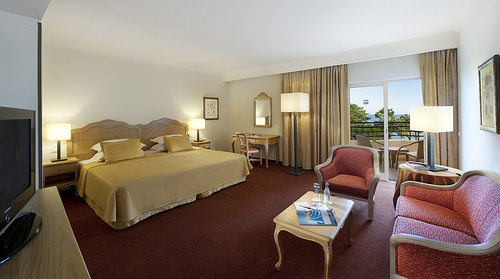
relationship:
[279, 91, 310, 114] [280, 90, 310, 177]
lamp shade top of floor lamp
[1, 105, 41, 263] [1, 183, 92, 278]
television on top of table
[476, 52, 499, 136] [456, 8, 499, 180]
art mounted on wall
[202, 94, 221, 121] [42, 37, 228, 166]
art mounted on wall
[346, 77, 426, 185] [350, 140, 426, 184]
french doors leading to deck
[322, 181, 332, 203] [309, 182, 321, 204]
bottle next to glass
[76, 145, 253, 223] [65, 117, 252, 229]
bed spread on top of bed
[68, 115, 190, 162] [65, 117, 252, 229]
headboard on back of bed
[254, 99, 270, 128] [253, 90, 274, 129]
mirror has frame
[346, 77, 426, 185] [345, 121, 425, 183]
french doors looking out to balcony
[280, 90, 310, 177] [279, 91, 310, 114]
floor lamp with lamp shade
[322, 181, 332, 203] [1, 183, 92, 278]
bottle on top of table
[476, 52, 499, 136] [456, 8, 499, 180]
art hanging on wall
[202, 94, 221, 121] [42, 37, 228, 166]
art hanging on wall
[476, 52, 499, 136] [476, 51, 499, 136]
art has frame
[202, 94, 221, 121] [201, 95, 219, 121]
art has frame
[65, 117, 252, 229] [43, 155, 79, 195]
bed next to nightstand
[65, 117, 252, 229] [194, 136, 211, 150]
bed next to nightstand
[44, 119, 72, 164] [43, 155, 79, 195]
lamp on top of nightstand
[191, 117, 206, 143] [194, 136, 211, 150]
lamp on top of nightstand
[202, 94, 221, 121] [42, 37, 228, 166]
art hung on wall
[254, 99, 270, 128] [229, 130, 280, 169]
mirror above desk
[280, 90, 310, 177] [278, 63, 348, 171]
floor lamp in front of curtains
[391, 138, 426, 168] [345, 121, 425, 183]
chair inside of balcony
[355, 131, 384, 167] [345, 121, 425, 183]
chair inside of balcony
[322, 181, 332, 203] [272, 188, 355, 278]
bottle on top of coffee table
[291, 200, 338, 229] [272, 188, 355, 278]
magazine on top of coffee table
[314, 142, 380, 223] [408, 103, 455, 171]
armchair next to lamp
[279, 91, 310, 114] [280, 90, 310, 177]
lamp shade on top of floor lamp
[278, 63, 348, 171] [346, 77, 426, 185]
curtains covering french doors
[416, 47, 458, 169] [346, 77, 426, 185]
curtains covering french doors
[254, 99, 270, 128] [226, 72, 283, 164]
mirror hung on wall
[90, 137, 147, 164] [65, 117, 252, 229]
pillows on top of bed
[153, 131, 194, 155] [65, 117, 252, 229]
pillows on top of bed